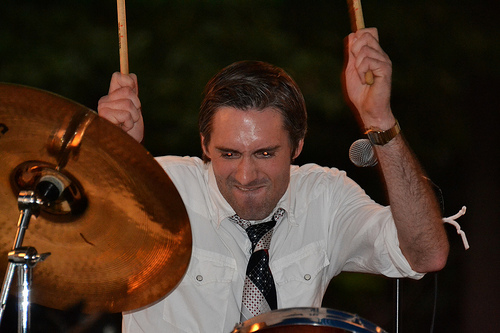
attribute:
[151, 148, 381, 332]
shirt — white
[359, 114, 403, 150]
watch — gold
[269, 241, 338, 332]
pocket — white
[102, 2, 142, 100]
drumstick — wooden, woodeny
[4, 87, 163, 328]
cymbal — gold, bronze